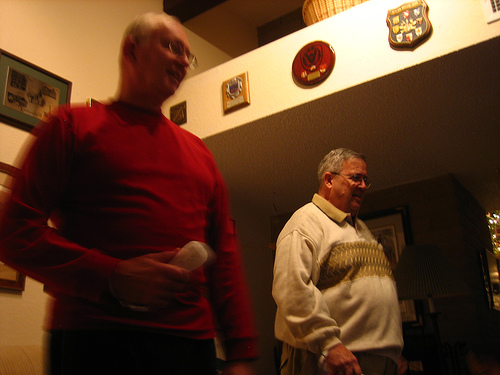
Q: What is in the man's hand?
A: Game controller.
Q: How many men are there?
A: Two.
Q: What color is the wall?
A: White.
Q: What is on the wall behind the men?
A: Pictures.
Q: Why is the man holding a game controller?
A: Playing.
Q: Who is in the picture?
A: The men.